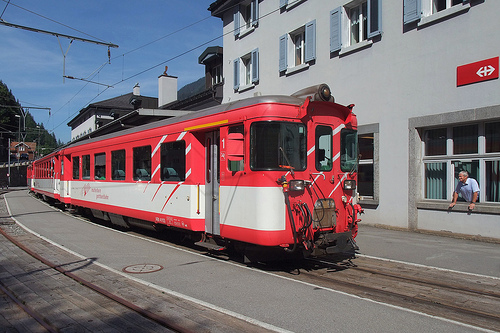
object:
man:
[448, 170, 480, 210]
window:
[401, 0, 487, 31]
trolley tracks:
[267, 253, 499, 333]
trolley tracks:
[0, 194, 295, 330]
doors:
[204, 129, 221, 236]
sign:
[455, 55, 499, 88]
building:
[206, 0, 500, 245]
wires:
[35, 0, 306, 134]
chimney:
[157, 74, 179, 108]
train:
[26, 82, 367, 269]